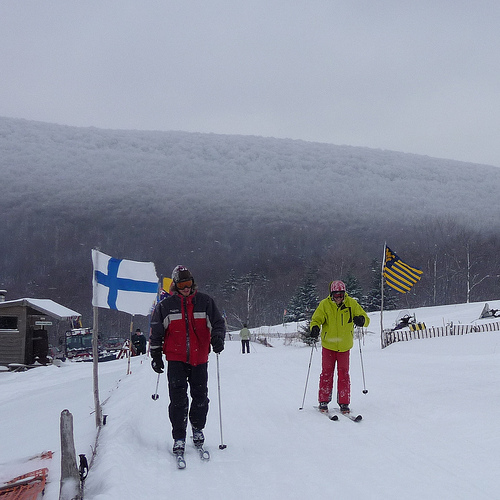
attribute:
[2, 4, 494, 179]
sky — overcast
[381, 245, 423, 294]
flag — striped, yellow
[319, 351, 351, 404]
pants — red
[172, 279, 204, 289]
goggles — pair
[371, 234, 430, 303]
flag — striped, blue, yellow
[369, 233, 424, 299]
flag — yellow, blue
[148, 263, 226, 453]
people — skiing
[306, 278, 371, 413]
people — skiing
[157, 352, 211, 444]
pants — dark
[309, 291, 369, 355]
jacket — yellow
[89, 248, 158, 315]
flag — blue, white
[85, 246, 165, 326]
flag — blue, white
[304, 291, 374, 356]
coat — green